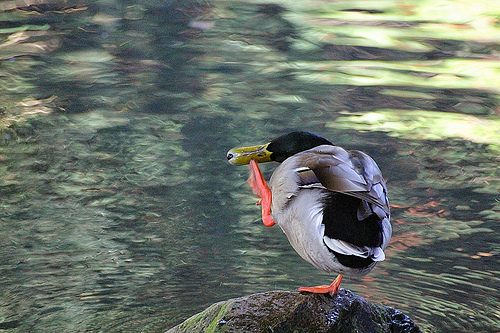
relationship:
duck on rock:
[211, 124, 487, 329] [224, 289, 356, 332]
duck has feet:
[211, 124, 487, 329] [235, 164, 273, 221]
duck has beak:
[211, 124, 487, 329] [228, 145, 278, 176]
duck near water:
[211, 124, 487, 329] [63, 40, 256, 276]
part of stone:
[186, 284, 253, 328] [224, 289, 356, 332]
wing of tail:
[315, 226, 390, 253] [309, 201, 420, 273]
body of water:
[40, 30, 344, 104] [63, 40, 256, 276]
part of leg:
[297, 286, 347, 305] [303, 270, 357, 303]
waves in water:
[142, 282, 228, 313] [63, 40, 256, 276]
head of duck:
[247, 130, 341, 169] [211, 124, 487, 329]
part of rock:
[186, 284, 253, 328] [165, 289, 418, 332]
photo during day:
[30, 21, 465, 309] [287, 4, 476, 90]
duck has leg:
[211, 124, 487, 329] [303, 270, 357, 303]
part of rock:
[186, 284, 253, 328] [224, 289, 356, 332]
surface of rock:
[283, 306, 361, 327] [165, 289, 418, 332]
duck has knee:
[211, 124, 487, 329] [257, 218, 286, 229]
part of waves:
[111, 235, 206, 272] [142, 282, 228, 313]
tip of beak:
[223, 152, 254, 176] [228, 145, 278, 176]